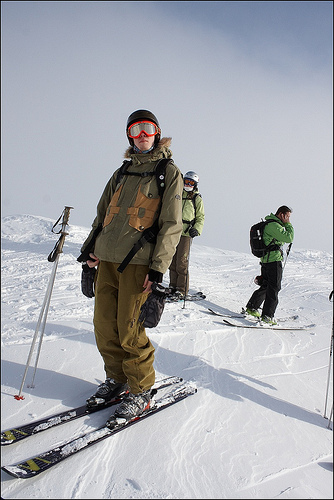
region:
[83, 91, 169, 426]
man wearing red safety goggles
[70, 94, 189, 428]
man wearing black safety helmet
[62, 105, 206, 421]
man wearing heavy olive green jacket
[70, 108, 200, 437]
man wearing thick brown pants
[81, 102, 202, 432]
man wearing backpack with black straps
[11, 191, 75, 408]
two ski poles in snow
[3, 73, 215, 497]
man wearing skis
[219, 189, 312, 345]
man wearing black backpack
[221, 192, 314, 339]
man wearing heavy green jacket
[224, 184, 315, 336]
man talking on cell phone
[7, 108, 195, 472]
a man standing on skis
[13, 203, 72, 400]
a set of metal ski poles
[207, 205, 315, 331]
a man standing on skis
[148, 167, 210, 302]
a man standing on skis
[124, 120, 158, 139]
red protective eyewear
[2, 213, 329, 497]
a snowy slope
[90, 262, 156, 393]
a pair of men's green jeans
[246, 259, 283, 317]
a pair of men's black pants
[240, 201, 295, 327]
a man talking on cell phone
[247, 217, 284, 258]
a large black backpack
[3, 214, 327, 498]
The ground is covered in snow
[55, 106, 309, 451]
Three people on snow skiing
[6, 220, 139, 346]
Snow tracks are in the snow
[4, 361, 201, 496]
Skis in the foreground are black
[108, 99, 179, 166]
Person is wearing a helmet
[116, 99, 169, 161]
The helmet is black in color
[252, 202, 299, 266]
Person is wearing a green hooded coat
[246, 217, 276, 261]
Person is wearing a black backpack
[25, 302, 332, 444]
Person is casting a shadow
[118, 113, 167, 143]
Goggles have a red rim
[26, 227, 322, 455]
picture taken outdoors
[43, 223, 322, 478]
picture taken during the day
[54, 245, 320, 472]
skiers on a mountain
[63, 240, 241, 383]
a skier has his gloves off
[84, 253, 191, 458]
the skier has kahki pans on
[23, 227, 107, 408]
the skier's poles are in the snow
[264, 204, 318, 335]
another skier is on his cell phone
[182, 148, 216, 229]
a skier is wearing a silver helmet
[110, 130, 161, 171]
the skier is wearing red goggles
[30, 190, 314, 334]
the skiers are on top of a mountain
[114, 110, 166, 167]
a man wearing red goggles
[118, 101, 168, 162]
a man wearing a black helmet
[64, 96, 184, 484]
a man wearing skis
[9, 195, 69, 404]
two ski poles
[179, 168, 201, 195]
a man wearing a silver helmet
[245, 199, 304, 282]
a man with his hand to his head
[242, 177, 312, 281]
a man wearing a green jacket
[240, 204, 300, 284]
a man with a black back pack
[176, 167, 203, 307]
a man wearing brown pants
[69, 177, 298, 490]
three men wearing skis